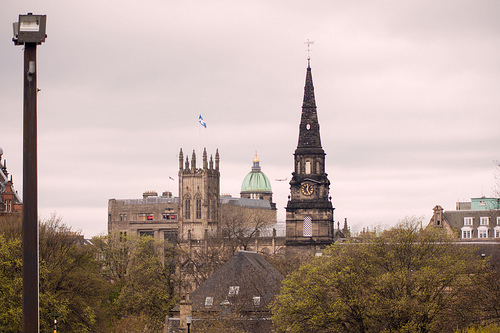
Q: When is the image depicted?
A: Cloudy day.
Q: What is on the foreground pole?
A: Lights.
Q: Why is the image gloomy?
A: Cloudy skies.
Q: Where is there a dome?
A: Middle of image.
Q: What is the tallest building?
A: Clock tower with steeple.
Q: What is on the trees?
A: Leaves.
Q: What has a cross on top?
A: Steeple.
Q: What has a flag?
A: Tower on left of dome.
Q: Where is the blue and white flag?
A: Above the tower.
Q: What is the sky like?
A: Clouded.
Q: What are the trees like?
A: Tall and green.